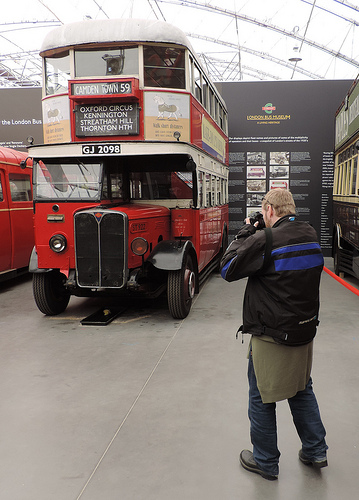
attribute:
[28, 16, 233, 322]
bus — old fashioned, double decker, large, red, huge, big, tall, white, old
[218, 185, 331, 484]
man — photographing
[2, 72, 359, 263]
wall — black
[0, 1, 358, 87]
ceiling — arched, glass, clear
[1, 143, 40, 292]
vehicle — old fashioned, small, orange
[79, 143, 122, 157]
number — gj 2098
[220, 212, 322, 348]
coat — black, blue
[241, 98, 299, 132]
sign — black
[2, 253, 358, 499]
floor — grey, stone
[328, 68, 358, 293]
bus — black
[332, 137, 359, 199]
windows — light yellow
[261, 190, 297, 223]
hair — brown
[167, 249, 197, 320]
tire — front left